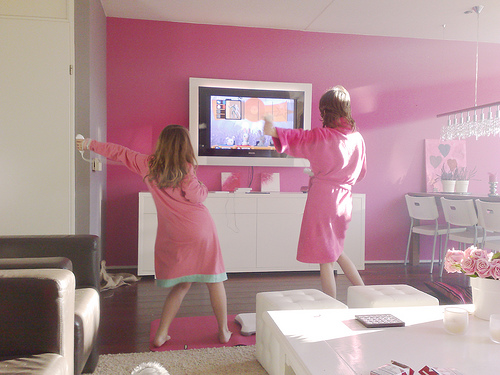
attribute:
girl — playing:
[82, 101, 240, 352]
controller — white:
[68, 126, 113, 179]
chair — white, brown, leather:
[2, 227, 113, 371]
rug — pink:
[143, 304, 449, 352]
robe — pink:
[91, 142, 243, 290]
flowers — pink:
[443, 242, 499, 295]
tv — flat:
[187, 69, 318, 168]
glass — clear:
[437, 303, 474, 341]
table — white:
[252, 295, 496, 372]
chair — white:
[400, 191, 491, 255]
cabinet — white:
[128, 179, 379, 281]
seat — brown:
[246, 269, 354, 365]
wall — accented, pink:
[111, 12, 452, 274]